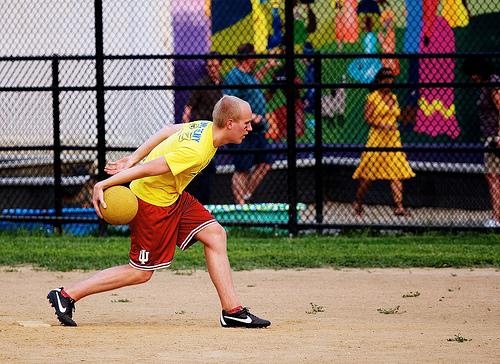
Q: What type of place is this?
A: It is a field.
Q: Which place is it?
A: It is a field.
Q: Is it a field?
A: Yes, it is a field.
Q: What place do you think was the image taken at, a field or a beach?
A: It was taken at a field.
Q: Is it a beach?
A: No, it is a field.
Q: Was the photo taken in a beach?
A: No, the picture was taken in a field.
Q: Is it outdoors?
A: Yes, it is outdoors.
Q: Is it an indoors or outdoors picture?
A: It is outdoors.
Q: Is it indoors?
A: No, it is outdoors.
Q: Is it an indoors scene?
A: No, it is outdoors.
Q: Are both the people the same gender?
A: No, they are both male and female.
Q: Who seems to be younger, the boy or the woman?
A: The boy is younger than the woman.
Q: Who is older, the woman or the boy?
A: The woman is older than the boy.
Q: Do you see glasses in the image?
A: No, there are no glasses.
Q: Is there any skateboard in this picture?
A: No, there are no skateboards.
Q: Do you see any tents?
A: No, there are no tents.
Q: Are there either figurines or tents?
A: No, there are no tents or figurines.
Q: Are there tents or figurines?
A: No, there are no tents or figurines.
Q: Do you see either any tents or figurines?
A: No, there are no tents or figurines.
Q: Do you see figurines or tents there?
A: No, there are no tents or figurines.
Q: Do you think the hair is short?
A: Yes, the hair is short.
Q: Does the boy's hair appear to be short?
A: Yes, the hair is short.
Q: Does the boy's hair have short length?
A: Yes, the hair is short.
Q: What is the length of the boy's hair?
A: The hair is short.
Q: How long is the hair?
A: The hair is short.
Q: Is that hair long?
A: No, the hair is short.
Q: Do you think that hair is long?
A: No, the hair is short.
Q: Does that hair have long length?
A: No, the hair is short.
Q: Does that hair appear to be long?
A: No, the hair is short.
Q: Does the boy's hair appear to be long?
A: No, the hair is short.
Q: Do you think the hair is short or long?
A: The hair is short.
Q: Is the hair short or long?
A: The hair is short.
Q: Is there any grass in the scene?
A: Yes, there is grass.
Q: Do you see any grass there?
A: Yes, there is grass.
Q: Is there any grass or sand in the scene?
A: Yes, there is grass.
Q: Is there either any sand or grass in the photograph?
A: Yes, there is grass.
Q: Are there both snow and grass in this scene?
A: No, there is grass but no snow.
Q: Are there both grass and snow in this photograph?
A: No, there is grass but no snow.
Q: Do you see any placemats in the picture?
A: No, there are no placemats.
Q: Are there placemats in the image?
A: No, there are no placemats.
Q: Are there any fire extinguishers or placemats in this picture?
A: No, there are no placemats or fire extinguishers.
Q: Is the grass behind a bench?
A: No, the grass is behind the boy.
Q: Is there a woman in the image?
A: Yes, there is a woman.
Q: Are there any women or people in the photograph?
A: Yes, there is a woman.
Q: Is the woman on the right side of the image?
A: Yes, the woman is on the right of the image.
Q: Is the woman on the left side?
A: No, the woman is on the right of the image.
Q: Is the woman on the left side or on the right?
A: The woman is on the right of the image.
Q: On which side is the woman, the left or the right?
A: The woman is on the right of the image.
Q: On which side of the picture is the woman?
A: The woman is on the right of the image.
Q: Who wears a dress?
A: The woman wears a dress.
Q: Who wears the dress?
A: The woman wears a dress.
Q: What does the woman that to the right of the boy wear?
A: The woman wears a dress.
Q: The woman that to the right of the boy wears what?
A: The woman wears a dress.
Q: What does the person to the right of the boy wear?
A: The woman wears a dress.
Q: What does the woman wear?
A: The woman wears a dress.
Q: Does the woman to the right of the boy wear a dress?
A: Yes, the woman wears a dress.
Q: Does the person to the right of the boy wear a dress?
A: Yes, the woman wears a dress.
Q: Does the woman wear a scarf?
A: No, the woman wears a dress.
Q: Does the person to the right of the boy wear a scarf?
A: No, the woman wears a dress.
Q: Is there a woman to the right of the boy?
A: Yes, there is a woman to the right of the boy.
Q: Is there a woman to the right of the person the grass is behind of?
A: Yes, there is a woman to the right of the boy.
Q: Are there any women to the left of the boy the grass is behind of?
A: No, the woman is to the right of the boy.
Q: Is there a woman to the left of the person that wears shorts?
A: No, the woman is to the right of the boy.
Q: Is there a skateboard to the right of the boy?
A: No, there is a woman to the right of the boy.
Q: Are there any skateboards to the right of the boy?
A: No, there is a woman to the right of the boy.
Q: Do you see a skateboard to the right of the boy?
A: No, there is a woman to the right of the boy.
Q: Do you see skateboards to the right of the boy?
A: No, there is a woman to the right of the boy.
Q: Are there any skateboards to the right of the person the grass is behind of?
A: No, there is a woman to the right of the boy.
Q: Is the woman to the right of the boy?
A: Yes, the woman is to the right of the boy.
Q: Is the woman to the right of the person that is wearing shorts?
A: Yes, the woman is to the right of the boy.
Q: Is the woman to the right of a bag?
A: No, the woman is to the right of the boy.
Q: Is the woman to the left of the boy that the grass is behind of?
A: No, the woman is to the right of the boy.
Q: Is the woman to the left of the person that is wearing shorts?
A: No, the woman is to the right of the boy.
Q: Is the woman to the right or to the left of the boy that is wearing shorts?
A: The woman is to the right of the boy.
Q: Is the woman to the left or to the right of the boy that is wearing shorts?
A: The woman is to the right of the boy.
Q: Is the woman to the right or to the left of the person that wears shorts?
A: The woman is to the right of the boy.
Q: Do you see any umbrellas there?
A: No, there are no umbrellas.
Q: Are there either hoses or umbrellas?
A: No, there are no umbrellas or hoses.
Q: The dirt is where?
A: The dirt is in the field.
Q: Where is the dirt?
A: The dirt is in the field.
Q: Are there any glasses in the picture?
A: No, there are no glasses.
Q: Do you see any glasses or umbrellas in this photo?
A: No, there are no glasses or umbrellas.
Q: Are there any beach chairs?
A: No, there are no beach chairs.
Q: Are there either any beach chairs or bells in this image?
A: No, there are no beach chairs or bells.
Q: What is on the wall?
A: The painting is on the wall.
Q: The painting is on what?
A: The painting is on the wall.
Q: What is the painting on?
A: The painting is on the wall.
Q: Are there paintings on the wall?
A: Yes, there is a painting on the wall.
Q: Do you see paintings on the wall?
A: Yes, there is a painting on the wall.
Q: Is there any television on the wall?
A: No, there is a painting on the wall.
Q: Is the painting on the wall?
A: Yes, the painting is on the wall.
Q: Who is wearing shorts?
A: The boy is wearing shorts.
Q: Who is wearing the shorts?
A: The boy is wearing shorts.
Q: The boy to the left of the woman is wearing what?
A: The boy is wearing shorts.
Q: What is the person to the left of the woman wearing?
A: The boy is wearing shorts.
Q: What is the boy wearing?
A: The boy is wearing shorts.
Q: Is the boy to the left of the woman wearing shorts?
A: Yes, the boy is wearing shorts.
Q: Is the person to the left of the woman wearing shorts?
A: Yes, the boy is wearing shorts.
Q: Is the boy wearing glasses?
A: No, the boy is wearing shorts.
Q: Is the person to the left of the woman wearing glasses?
A: No, the boy is wearing shorts.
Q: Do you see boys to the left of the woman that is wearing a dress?
A: Yes, there is a boy to the left of the woman.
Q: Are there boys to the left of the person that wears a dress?
A: Yes, there is a boy to the left of the woman.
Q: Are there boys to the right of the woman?
A: No, the boy is to the left of the woman.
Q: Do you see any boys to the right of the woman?
A: No, the boy is to the left of the woman.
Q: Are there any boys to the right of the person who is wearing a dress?
A: No, the boy is to the left of the woman.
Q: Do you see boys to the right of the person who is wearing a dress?
A: No, the boy is to the left of the woman.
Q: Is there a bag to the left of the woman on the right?
A: No, there is a boy to the left of the woman.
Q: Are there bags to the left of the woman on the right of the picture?
A: No, there is a boy to the left of the woman.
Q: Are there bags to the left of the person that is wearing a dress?
A: No, there is a boy to the left of the woman.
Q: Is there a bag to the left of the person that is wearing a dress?
A: No, there is a boy to the left of the woman.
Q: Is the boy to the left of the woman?
A: Yes, the boy is to the left of the woman.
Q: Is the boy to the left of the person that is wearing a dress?
A: Yes, the boy is to the left of the woman.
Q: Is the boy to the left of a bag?
A: No, the boy is to the left of the woman.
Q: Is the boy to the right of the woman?
A: No, the boy is to the left of the woman.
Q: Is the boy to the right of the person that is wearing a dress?
A: No, the boy is to the left of the woman.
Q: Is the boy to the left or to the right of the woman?
A: The boy is to the left of the woman.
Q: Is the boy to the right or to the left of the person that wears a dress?
A: The boy is to the left of the woman.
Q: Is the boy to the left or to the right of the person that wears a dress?
A: The boy is to the left of the woman.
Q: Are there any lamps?
A: No, there are no lamps.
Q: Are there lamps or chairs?
A: No, there are no lamps or chairs.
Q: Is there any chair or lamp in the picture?
A: No, there are no lamps or chairs.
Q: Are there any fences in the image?
A: Yes, there is a fence.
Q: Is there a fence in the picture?
A: Yes, there is a fence.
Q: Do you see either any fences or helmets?
A: Yes, there is a fence.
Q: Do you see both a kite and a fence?
A: No, there is a fence but no kites.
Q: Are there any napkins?
A: No, there are no napkins.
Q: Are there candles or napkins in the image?
A: No, there are no napkins or candles.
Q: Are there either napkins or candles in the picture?
A: No, there are no napkins or candles.